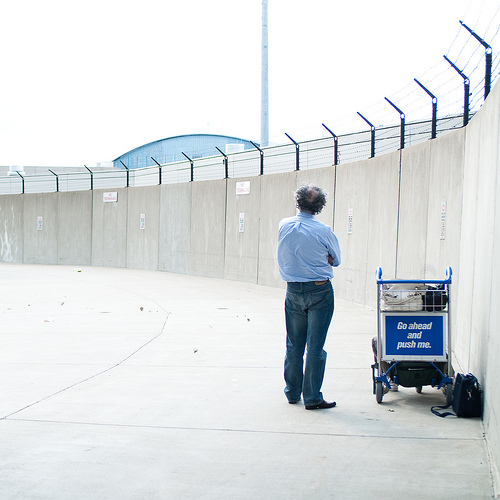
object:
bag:
[431, 372, 483, 418]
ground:
[0, 264, 493, 500]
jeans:
[282, 283, 333, 406]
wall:
[7, 182, 209, 264]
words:
[397, 322, 433, 350]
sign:
[381, 312, 447, 362]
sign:
[374, 309, 452, 361]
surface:
[160, 236, 229, 286]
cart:
[370, 265, 452, 404]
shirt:
[276, 211, 340, 282]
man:
[276, 187, 340, 409]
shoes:
[290, 397, 301, 404]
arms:
[325, 236, 341, 266]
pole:
[260, 0, 269, 147]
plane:
[10, 286, 273, 408]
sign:
[236, 181, 251, 194]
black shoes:
[306, 401, 337, 410]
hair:
[294, 184, 325, 214]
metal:
[376, 268, 394, 284]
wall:
[452, 79, 496, 377]